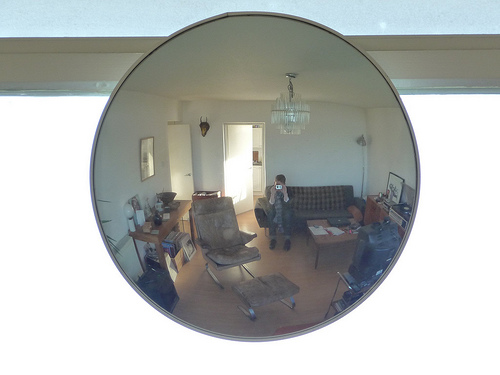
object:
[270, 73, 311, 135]
chandelier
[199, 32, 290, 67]
ceiling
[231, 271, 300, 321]
ottoman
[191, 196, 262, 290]
chair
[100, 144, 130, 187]
wall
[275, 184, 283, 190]
camera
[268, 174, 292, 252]
person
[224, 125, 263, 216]
doorway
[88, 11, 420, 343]
mirror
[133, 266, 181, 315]
suitcase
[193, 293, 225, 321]
floor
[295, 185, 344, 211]
blanket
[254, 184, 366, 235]
couch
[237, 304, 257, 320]
metal legs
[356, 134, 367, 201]
lamp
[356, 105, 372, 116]
corner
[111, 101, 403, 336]
room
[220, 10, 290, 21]
edge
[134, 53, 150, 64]
part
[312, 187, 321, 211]
part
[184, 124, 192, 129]
edge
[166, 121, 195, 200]
door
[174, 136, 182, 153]
side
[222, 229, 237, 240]
part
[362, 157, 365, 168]
part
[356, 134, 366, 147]
light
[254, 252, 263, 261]
edge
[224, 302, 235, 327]
part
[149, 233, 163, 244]
part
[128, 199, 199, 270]
table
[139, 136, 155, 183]
frame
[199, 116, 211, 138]
statue